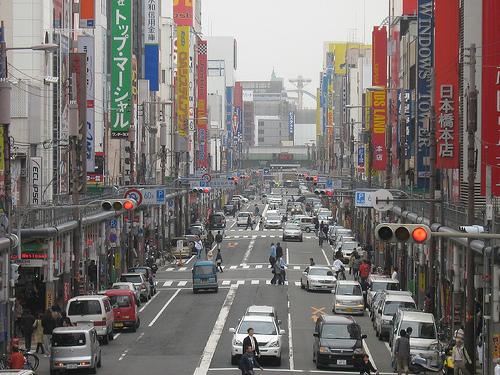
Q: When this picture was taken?
A: During the day.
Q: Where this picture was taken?
A: In a street.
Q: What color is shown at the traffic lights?
A: Is red.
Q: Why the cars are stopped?
A: Because the traffic lights are indicating that they should stop.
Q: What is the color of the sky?
A: Is gray.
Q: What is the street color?
A: Is black and white.